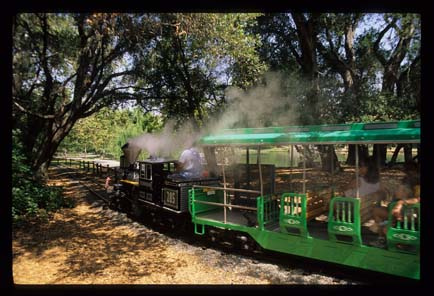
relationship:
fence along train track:
[59, 159, 113, 176] [59, 159, 107, 207]